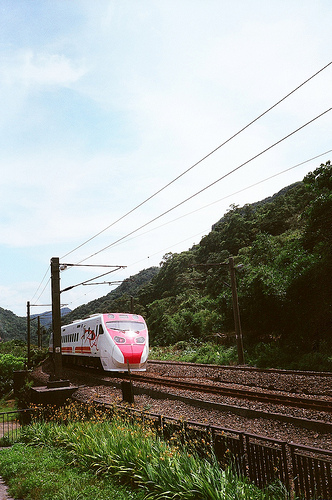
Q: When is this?
A: Daytime.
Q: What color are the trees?
A: Green.